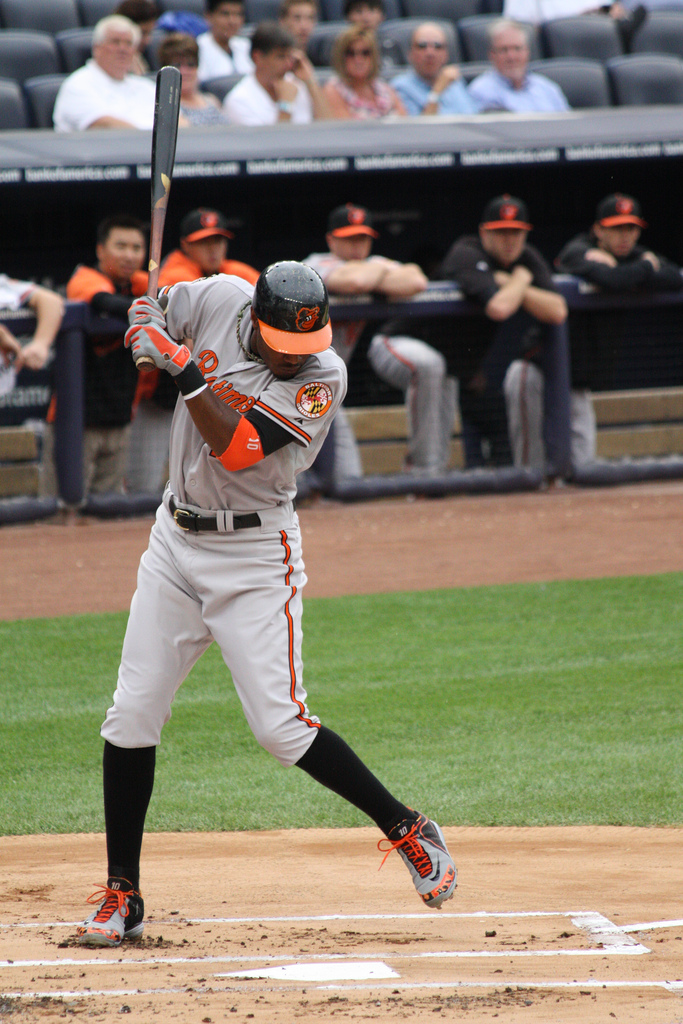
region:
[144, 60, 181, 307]
Black baseball bat being held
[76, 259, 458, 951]
Baseball player up to bat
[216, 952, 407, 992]
Home plate in sand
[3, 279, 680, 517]
Fence along baseball field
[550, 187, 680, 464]
Baseball player watching game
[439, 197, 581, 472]
Baseball player crossing arms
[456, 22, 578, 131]
Man in light blue shirt watching game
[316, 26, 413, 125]
Woman wearing sunglasses in bleachers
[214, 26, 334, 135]
Man watching baseball game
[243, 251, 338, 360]
Black and orange baseball helmet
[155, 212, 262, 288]
person is in a ball park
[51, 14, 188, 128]
person is in a ball park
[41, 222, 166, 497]
person is in a ball park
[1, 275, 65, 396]
person is in a ball park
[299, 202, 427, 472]
person is in a ball park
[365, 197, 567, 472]
person is in a ball park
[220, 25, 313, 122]
person is in a ball park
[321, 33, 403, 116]
person is in a ball park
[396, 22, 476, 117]
person is in a ball park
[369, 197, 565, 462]
player in black uniform top leans on fence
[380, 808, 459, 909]
gray and black cleat with orange laces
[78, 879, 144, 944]
gray and black cleat with orange laces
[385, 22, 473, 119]
man in blue shirt wears black sunglasses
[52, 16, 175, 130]
old man with white hair wears white shirt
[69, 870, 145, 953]
black and grey shoe with orange shoelaces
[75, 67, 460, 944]
baseball player swinging a baseball bat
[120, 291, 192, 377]
grey and orange gloves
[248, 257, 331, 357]
shiny black and orange helmet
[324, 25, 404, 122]
woman wearing black sunglasses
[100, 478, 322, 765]
black belt holding up white pants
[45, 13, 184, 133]
older man wearing white shirt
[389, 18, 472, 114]
bald man wearing blue shirt and sunglasses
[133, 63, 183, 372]
metal bat with gold star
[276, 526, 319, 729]
black and orange pant stripe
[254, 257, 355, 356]
The man is wearing a black helmet.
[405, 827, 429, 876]
The shoelaces are orange.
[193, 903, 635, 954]
The line is white.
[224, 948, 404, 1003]
The plate on the ground.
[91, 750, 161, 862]
The sock is black.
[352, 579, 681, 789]
The grass is green.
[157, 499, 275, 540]
The man is wearing a black belt.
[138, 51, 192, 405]
The man is holding a bat.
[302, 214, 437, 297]
The man arm is folded.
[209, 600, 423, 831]
leg of baseball player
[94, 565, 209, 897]
leg of baseball player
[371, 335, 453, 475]
leg of baseball player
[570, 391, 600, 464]
leg of baseball player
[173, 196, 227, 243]
black and orange colored baseball hat on player in dugout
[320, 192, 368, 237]
black and orange colored baseball hat on player in dugout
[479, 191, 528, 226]
black and orange colored baseball hat on player in dugout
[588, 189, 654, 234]
black and orange colored baseball hat on player in dugout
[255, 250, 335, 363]
helmet on batter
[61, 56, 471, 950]
batter holding a bat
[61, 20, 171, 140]
fan sitting in stands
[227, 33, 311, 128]
fan sitting in stands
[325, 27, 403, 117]
fan sitting in stands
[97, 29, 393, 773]
the man is playing basball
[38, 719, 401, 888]
the socks are black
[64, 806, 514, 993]
the shoes are cleats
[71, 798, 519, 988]
the shoes are gray and orange